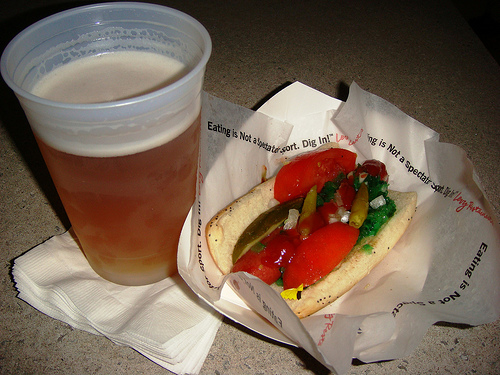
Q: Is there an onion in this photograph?
A: Yes, there is an onion.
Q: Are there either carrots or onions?
A: Yes, there is an onion.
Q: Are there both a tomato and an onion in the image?
A: Yes, there are both an onion and a tomato.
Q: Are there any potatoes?
A: No, there are no potatoes.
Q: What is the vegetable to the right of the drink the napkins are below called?
A: The vegetable is an onion.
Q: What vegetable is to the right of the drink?
A: The vegetable is an onion.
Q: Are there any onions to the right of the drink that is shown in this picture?
A: Yes, there is an onion to the right of the drink.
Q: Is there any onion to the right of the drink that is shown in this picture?
A: Yes, there is an onion to the right of the drink.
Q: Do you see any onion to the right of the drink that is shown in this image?
A: Yes, there is an onion to the right of the drink.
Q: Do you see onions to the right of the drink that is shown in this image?
A: Yes, there is an onion to the right of the drink.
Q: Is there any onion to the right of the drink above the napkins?
A: Yes, there is an onion to the right of the drink.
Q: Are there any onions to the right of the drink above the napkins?
A: Yes, there is an onion to the right of the drink.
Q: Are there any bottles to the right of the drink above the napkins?
A: No, there is an onion to the right of the drink.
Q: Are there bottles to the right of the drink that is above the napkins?
A: No, there is an onion to the right of the drink.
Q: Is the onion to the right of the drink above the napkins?
A: Yes, the onion is to the right of the drink.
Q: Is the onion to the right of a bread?
A: No, the onion is to the right of the drink.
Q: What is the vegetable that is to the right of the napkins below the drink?
A: The vegetable is an onion.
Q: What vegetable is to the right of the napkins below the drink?
A: The vegetable is an onion.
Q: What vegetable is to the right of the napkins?
A: The vegetable is an onion.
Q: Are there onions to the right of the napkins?
A: Yes, there is an onion to the right of the napkins.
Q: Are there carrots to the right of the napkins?
A: No, there is an onion to the right of the napkins.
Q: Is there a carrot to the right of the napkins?
A: No, there is an onion to the right of the napkins.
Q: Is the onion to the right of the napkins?
A: Yes, the onion is to the right of the napkins.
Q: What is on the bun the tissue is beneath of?
A: The onion is on the bun.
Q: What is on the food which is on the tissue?
A: The onion is on the bun.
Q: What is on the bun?
A: The onion is on the bun.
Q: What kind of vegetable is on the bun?
A: The vegetable is an onion.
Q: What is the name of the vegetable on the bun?
A: The vegetable is an onion.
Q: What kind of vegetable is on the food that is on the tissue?
A: The vegetable is an onion.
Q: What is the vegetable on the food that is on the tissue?
A: The vegetable is an onion.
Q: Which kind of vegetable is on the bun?
A: The vegetable is an onion.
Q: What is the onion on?
A: The onion is on the bun.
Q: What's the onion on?
A: The onion is on the bun.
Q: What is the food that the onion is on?
A: The food is a bun.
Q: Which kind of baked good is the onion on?
A: The onion is on the bun.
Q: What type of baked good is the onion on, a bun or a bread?
A: The onion is on a bun.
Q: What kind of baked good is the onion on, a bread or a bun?
A: The onion is on a bun.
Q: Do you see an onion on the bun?
A: Yes, there is an onion on the bun.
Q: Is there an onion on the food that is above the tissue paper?
A: Yes, there is an onion on the bun.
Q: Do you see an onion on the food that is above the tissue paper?
A: Yes, there is an onion on the bun.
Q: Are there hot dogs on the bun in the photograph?
A: No, there is an onion on the bun.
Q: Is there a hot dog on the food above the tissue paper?
A: No, there is an onion on the bun.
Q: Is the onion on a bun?
A: Yes, the onion is on a bun.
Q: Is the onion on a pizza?
A: No, the onion is on a bun.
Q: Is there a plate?
A: No, there are no plates.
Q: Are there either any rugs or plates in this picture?
A: No, there are no plates or rugs.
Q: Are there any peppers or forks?
A: Yes, there is a pepper.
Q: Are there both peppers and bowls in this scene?
A: No, there is a pepper but no bowls.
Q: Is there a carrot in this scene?
A: No, there are no carrots.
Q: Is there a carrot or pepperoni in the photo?
A: No, there are no carrots or pepperoni.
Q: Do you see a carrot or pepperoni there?
A: No, there are no carrots or pepperoni.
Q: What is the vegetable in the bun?
A: The vegetable is a pepper.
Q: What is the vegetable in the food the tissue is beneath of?
A: The vegetable is a pepper.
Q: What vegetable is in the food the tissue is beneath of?
A: The vegetable is a pepper.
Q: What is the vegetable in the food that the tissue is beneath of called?
A: The vegetable is a pepper.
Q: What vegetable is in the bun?
A: The vegetable is a pepper.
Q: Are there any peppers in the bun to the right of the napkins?
A: Yes, there is a pepper in the bun.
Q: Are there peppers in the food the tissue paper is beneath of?
A: Yes, there is a pepper in the bun.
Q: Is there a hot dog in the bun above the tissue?
A: No, there is a pepper in the bun.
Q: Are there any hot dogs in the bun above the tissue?
A: No, there is a pepper in the bun.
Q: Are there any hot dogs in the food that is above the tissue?
A: No, there is a pepper in the bun.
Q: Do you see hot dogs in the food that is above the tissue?
A: No, there is a pepper in the bun.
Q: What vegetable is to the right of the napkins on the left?
A: The vegetable is a pepper.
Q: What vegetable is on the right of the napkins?
A: The vegetable is a pepper.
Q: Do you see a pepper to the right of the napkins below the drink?
A: Yes, there is a pepper to the right of the napkins.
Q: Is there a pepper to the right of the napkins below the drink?
A: Yes, there is a pepper to the right of the napkins.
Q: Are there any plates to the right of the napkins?
A: No, there is a pepper to the right of the napkins.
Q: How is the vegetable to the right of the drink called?
A: The vegetable is a pepper.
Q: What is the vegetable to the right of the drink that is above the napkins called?
A: The vegetable is a pepper.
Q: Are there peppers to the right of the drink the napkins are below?
A: Yes, there is a pepper to the right of the drink.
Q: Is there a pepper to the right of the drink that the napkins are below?
A: Yes, there is a pepper to the right of the drink.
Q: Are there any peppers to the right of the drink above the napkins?
A: Yes, there is a pepper to the right of the drink.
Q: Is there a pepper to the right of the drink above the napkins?
A: Yes, there is a pepper to the right of the drink.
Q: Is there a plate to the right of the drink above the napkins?
A: No, there is a pepper to the right of the drink.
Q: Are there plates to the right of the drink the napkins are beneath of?
A: No, there is a pepper to the right of the drink.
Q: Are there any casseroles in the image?
A: No, there are no casseroles.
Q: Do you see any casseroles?
A: No, there are no casseroles.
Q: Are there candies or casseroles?
A: No, there are no casseroles or candies.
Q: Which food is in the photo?
A: The food is a bun.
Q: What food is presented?
A: The food is a bun.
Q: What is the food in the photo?
A: The food is a bun.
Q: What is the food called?
A: The food is a bun.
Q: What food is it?
A: The food is a bun.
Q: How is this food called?
A: This is a bun.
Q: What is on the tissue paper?
A: The bun is on the tissue paper.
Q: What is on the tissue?
A: The bun is on the tissue paper.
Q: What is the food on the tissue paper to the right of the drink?
A: The food is a bun.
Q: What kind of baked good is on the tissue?
A: The food is a bun.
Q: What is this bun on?
A: The bun is on the tissue.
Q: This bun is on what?
A: The bun is on the tissue.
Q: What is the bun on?
A: The bun is on the tissue.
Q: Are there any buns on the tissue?
A: Yes, there is a bun on the tissue.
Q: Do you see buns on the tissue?
A: Yes, there is a bun on the tissue.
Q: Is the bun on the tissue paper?
A: Yes, the bun is on the tissue paper.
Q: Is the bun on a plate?
A: No, the bun is on the tissue paper.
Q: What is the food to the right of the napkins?
A: The food is a bun.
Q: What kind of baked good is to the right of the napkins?
A: The food is a bun.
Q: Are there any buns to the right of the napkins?
A: Yes, there is a bun to the right of the napkins.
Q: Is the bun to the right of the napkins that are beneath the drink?
A: Yes, the bun is to the right of the napkins.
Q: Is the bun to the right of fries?
A: No, the bun is to the right of the napkins.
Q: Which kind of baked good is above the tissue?
A: The food is a bun.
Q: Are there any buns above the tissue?
A: Yes, there is a bun above the tissue.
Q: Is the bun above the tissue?
A: Yes, the bun is above the tissue.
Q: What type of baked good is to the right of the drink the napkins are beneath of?
A: The food is a bun.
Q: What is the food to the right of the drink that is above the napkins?
A: The food is a bun.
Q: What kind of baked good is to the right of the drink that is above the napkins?
A: The food is a bun.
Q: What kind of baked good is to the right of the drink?
A: The food is a bun.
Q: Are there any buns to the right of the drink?
A: Yes, there is a bun to the right of the drink.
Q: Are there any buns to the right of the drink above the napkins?
A: Yes, there is a bun to the right of the drink.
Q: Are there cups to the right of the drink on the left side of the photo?
A: No, there is a bun to the right of the drink.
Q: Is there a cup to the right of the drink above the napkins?
A: No, there is a bun to the right of the drink.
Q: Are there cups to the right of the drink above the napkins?
A: No, there is a bun to the right of the drink.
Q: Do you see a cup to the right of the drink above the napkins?
A: No, there is a bun to the right of the drink.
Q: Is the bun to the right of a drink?
A: Yes, the bun is to the right of a drink.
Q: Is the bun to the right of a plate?
A: No, the bun is to the right of a drink.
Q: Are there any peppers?
A: Yes, there are peppers.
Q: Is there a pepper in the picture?
A: Yes, there are peppers.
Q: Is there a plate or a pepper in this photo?
A: Yes, there are peppers.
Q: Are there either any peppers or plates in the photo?
A: Yes, there are peppers.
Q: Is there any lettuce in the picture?
A: No, there is no lettuce.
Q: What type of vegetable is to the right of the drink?
A: The vegetables are peppers.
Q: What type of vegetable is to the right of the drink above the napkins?
A: The vegetables are peppers.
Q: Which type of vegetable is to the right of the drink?
A: The vegetables are peppers.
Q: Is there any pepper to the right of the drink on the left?
A: Yes, there are peppers to the right of the drink.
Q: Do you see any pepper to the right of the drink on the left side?
A: Yes, there are peppers to the right of the drink.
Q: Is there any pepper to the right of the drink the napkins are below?
A: Yes, there are peppers to the right of the drink.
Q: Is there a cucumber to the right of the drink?
A: No, there are peppers to the right of the drink.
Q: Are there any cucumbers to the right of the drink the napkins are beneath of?
A: No, there are peppers to the right of the drink.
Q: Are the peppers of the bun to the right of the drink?
A: Yes, the peppers are to the right of the drink.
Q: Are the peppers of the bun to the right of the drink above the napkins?
A: Yes, the peppers are to the right of the drink.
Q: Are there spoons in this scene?
A: No, there are no spoons.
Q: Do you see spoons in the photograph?
A: No, there are no spoons.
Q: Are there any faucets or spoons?
A: No, there are no spoons or faucets.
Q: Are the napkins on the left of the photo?
A: Yes, the napkins are on the left of the image.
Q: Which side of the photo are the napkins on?
A: The napkins are on the left of the image.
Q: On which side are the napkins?
A: The napkins are on the left of the image.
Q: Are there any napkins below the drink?
A: Yes, there are napkins below the drink.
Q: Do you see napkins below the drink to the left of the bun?
A: Yes, there are napkins below the drink.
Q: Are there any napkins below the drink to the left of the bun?
A: Yes, there are napkins below the drink.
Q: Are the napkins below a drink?
A: Yes, the napkins are below a drink.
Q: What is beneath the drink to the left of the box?
A: The napkins are beneath the drink.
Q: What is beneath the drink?
A: The napkins are beneath the drink.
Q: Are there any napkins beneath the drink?
A: Yes, there are napkins beneath the drink.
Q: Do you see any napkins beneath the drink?
A: Yes, there are napkins beneath the drink.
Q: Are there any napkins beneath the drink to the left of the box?
A: Yes, there are napkins beneath the drink.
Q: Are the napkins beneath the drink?
A: Yes, the napkins are beneath the drink.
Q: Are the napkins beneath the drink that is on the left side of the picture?
A: Yes, the napkins are beneath the drink.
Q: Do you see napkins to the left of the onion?
A: Yes, there are napkins to the left of the onion.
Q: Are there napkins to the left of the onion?
A: Yes, there are napkins to the left of the onion.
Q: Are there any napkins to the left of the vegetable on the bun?
A: Yes, there are napkins to the left of the onion.